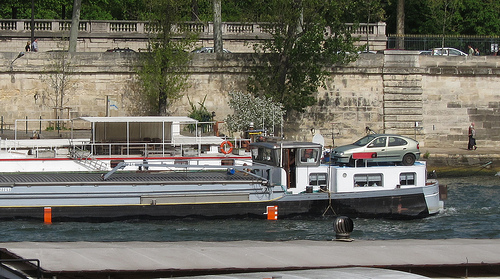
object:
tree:
[223, 85, 283, 140]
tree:
[128, 6, 217, 122]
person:
[466, 122, 477, 152]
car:
[330, 135, 421, 165]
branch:
[189, 7, 209, 24]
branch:
[293, 13, 308, 40]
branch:
[240, 16, 287, 43]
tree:
[231, 16, 370, 144]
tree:
[413, 2, 497, 51]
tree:
[181, 95, 213, 137]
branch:
[289, 33, 367, 93]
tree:
[39, 45, 77, 131]